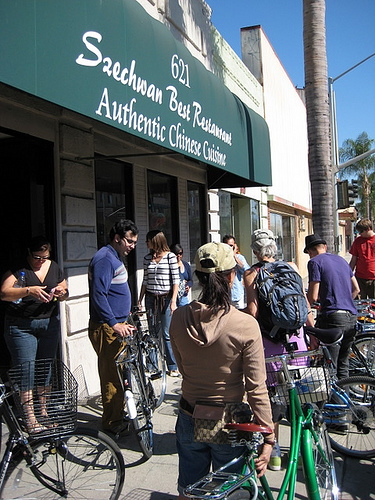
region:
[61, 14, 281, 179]
White letters on the sign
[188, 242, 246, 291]
The person is wearing a cap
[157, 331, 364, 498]
Bike is light green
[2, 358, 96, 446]
Basket on the bike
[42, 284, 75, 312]
Person's phone in hand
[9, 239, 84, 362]
She is looking at her phone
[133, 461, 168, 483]
This is pavement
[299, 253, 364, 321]
Shirt is dark blue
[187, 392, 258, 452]
Bag on the back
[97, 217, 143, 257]
Man has black hair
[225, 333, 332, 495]
the bike is green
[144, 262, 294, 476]
the jacket is brown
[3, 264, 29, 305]
a bottle of water in the lady's arm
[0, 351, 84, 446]
a basket on the front of the bike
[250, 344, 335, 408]
a basket on the front of a green bike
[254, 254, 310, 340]
a large light blue backpack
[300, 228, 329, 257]
a black hat on the man's head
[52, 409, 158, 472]
the shadow of a bicycle tire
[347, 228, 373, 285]
a red shirt on the man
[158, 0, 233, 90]
the shadow on the building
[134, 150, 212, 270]
a set of windows on the store front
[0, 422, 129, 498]
the tire of a bicycle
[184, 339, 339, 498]
A green and silver bicycle.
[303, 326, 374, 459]
A blue bicycle.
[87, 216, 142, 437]
A man in a blue shirt.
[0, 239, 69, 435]
A woman standing by a wall.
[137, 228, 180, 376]
A woman wearing a striped shirt.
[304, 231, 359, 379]
A man in a black hat and purple shirt.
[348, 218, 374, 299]
A man wearing a red shirt.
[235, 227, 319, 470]
A lady with a backpack.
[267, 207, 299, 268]
A large window.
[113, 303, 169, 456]
A black and white bicycle.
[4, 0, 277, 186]
green awning advertising Chinese food and Szechwan cuisine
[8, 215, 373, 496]
group of cyclists gathered outside restaurant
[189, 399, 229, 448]
Gucci bum bag worn by woman with dark hair with beige baseball cap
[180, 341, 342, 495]
green bike with basket held by dark haired woman in foreground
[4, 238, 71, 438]
slightly large woman standing in doorway wearing black tee shirt and holding phone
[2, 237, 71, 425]
woman with dark hair wearing denim capris and sunglasses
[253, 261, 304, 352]
large blue backpack on woman with gray hair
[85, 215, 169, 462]
man in blue shirt and brown pants holding black bike with white water bottle mounted on back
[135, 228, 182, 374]
woman with long brown hair and striped shirt walking by restaurant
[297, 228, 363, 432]
man nin purple shirt with black hat wearing black jeans